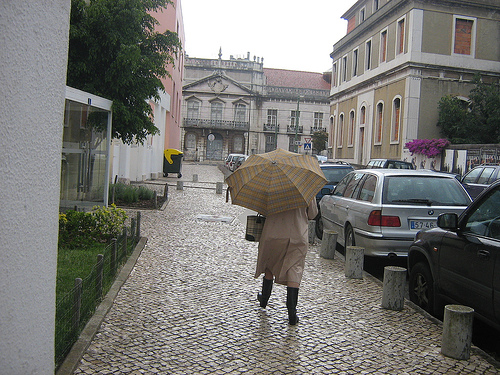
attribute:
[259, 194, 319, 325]
person — walking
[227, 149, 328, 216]
umbrella — plaid, grey, yellow, striped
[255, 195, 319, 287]
coat — beige, trench coat, tan, polyester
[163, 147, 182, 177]
bin — yellow, black, metal, green, small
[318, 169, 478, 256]
car — silver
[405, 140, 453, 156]
flowers — purple, pink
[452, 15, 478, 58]
window — boarded-up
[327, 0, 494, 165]
building — old, large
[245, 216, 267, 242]
bag — yellow, grey, black, white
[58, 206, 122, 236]
flowers — yellow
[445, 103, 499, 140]
leaves — green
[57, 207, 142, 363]
fence — metal, wood, small, black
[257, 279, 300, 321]
boots — black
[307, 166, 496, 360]
cars — parked